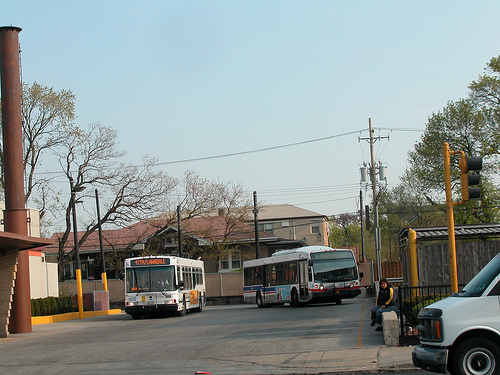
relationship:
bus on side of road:
[121, 256, 207, 314] [1, 296, 415, 375]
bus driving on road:
[242, 245, 361, 307] [1, 296, 415, 375]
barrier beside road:
[381, 309, 402, 347] [1, 296, 415, 375]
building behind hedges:
[29, 209, 58, 299] [31, 292, 75, 314]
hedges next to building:
[31, 292, 75, 314] [29, 209, 58, 299]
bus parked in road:
[121, 256, 207, 314] [1, 296, 415, 375]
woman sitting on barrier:
[368, 274, 395, 332] [381, 309, 402, 347]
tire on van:
[448, 333, 500, 374] [411, 253, 499, 374]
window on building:
[307, 220, 320, 236] [249, 203, 331, 247]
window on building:
[257, 221, 275, 235] [249, 203, 331, 247]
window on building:
[217, 247, 243, 273] [46, 220, 302, 282]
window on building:
[162, 230, 179, 249] [46, 220, 302, 282]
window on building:
[60, 260, 87, 282] [46, 220, 302, 282]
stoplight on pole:
[459, 149, 484, 203] [441, 141, 469, 297]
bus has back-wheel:
[242, 245, 361, 307] [255, 290, 264, 308]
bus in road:
[121, 256, 207, 314] [1, 296, 415, 375]